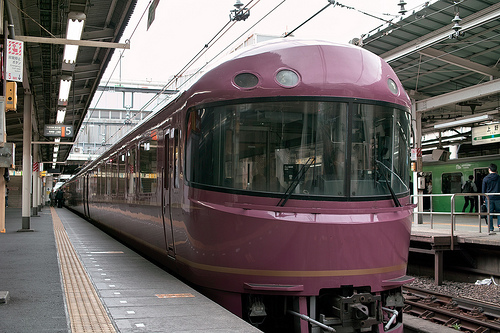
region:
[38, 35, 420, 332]
a purple train stopping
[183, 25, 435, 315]
front of a train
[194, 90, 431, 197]
wind shield of a train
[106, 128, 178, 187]
windows of a train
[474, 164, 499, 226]
person wearing blue shirt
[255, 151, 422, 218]
windshield wiper of train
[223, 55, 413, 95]
head lights of a train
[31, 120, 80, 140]
signs on a train station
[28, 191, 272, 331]
train station unload pathway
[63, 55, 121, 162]
power lines for train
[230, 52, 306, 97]
the round lights above the front windshield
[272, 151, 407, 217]
the wipers on the windshield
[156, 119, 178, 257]
the door to the train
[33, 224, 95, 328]
the train platform for the station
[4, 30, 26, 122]
the signs on the wall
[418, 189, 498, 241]
the guardrail on the platform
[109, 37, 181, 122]
the wires above the train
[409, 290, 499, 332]
the train tracks on the ground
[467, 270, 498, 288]
the white trash below the platform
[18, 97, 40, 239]
the steel beams holding up the canopy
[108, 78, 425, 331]
a train in the station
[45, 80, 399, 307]
it is pink in colour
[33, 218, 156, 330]
the pavement is black in colour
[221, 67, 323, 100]
the lights are off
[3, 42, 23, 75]
the sign is white in colour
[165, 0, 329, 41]
the sky is white in colour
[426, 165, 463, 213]
the house is green in colour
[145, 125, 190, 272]
the door is closed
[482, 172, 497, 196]
the jacket is black in colour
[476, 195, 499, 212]
the pants are blue in colour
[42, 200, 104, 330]
Yellow train station barrier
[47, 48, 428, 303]
Red train in station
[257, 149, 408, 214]
Windshield wipers of train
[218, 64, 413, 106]
Headlights of train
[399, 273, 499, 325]
Train tracks at train station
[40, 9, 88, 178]
Row of lights at train station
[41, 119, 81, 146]
Train station sign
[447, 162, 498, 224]
Passengers at train station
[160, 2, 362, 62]
Wires above train at train station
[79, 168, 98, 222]
Train doors